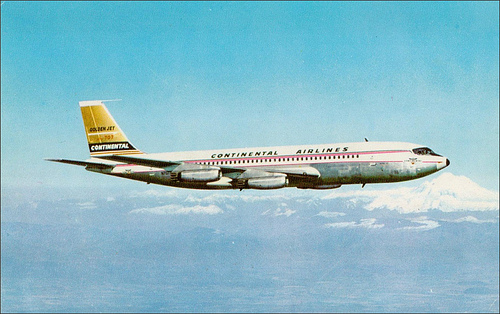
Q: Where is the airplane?
A: Sky.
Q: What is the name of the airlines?
A: Continental.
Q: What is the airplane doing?
A: Flying.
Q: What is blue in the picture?
A: The sky.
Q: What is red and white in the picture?
A: A plane.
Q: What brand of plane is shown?
A: Continental.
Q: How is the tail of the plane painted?
A: Gold and black.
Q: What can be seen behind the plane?
A: Mountains.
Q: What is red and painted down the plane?
A: A stripe.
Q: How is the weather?
A: Clear.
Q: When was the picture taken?
A: Afternoon.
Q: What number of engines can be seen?
A: Two.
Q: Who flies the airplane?
A: The pilot.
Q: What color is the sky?
A: Blue.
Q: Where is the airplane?
A: In the air.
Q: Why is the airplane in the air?
A: To get to it's destination.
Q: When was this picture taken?
A: During the day.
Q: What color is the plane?
A: White and yellow.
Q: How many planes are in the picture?
A: One.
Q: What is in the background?
A: Mountains.